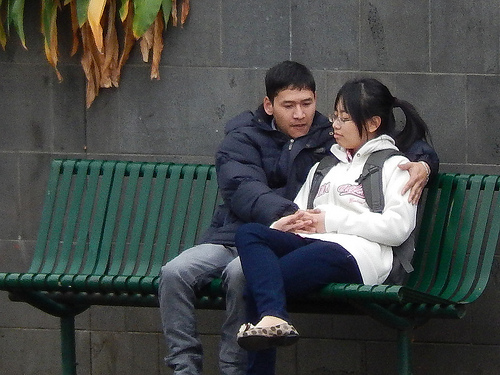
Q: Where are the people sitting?
A: Bench.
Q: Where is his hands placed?
A: Shoulders.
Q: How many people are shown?
A: Two.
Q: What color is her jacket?
A: White.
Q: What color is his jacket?
A: Blue.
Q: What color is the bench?
A: Green.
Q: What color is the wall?
A: Grey.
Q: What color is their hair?
A: Black.